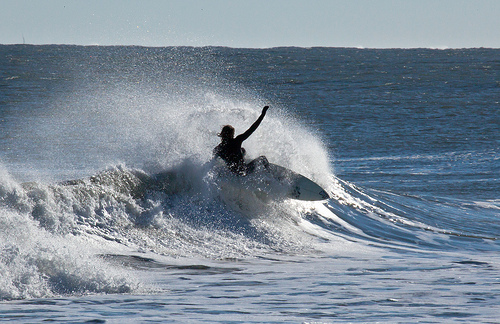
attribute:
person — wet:
[194, 111, 288, 189]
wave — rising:
[95, 192, 199, 258]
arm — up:
[248, 103, 280, 143]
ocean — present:
[373, 66, 494, 152]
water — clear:
[12, 43, 493, 323]